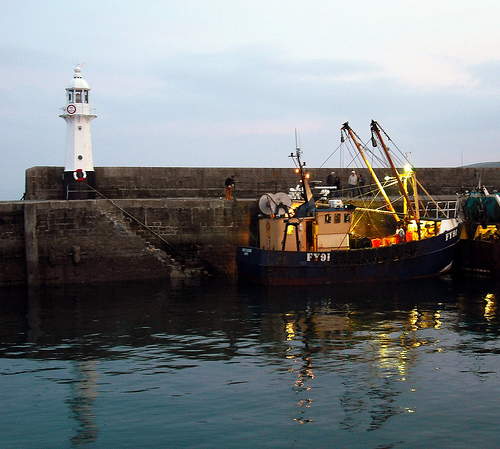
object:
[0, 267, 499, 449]
water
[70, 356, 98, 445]
refelction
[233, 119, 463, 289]
boat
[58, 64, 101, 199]
lighthouse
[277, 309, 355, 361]
reflection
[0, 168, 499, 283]
wall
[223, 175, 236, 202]
man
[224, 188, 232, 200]
pants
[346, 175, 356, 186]
shirt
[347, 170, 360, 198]
man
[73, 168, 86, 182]
life saver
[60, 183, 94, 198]
base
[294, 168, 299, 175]
light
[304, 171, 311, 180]
light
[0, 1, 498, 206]
sky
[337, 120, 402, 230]
crane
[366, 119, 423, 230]
crane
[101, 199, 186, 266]
rail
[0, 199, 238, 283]
pier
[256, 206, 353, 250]
room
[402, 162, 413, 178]
light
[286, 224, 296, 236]
sign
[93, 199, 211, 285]
stairway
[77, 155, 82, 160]
window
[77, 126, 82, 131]
window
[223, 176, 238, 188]
jacket